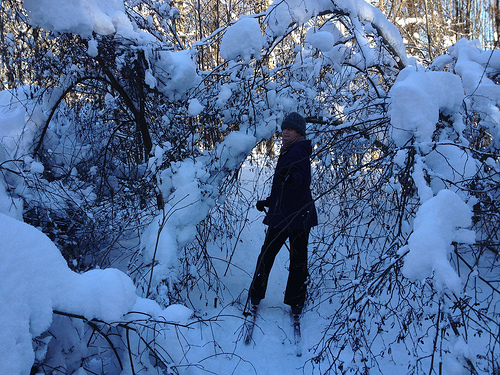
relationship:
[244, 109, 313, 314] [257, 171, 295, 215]
woman wears gloves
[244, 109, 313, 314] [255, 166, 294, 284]
woman holds poles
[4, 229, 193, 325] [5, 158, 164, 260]
snow on bushes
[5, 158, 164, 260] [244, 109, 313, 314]
bushes block woman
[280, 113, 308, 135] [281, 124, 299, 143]
hat on head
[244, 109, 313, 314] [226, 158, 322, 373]
woman on trail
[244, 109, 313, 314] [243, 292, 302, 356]
woman wears skis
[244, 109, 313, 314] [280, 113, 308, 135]
woman wears hat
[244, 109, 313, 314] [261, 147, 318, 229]
woman wears jacket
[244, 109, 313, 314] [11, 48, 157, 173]
woman surrounded by branches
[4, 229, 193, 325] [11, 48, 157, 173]
snow bends branches